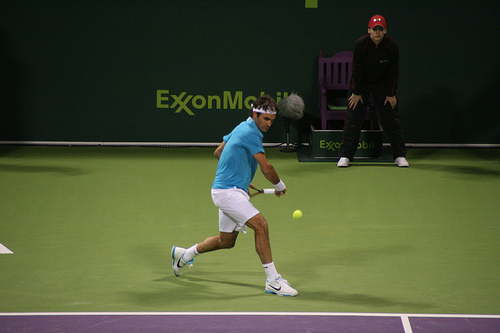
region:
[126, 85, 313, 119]
Exxon Mobile logo in background of sporting event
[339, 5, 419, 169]
man in red baseball cap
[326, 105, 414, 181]
dark pants with white sneakers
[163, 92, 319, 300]
male tennis player wearing white shorts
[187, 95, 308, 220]
man playing tennis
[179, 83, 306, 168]
man playing a sport wearing a white headband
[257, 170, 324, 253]
tennis ball in midair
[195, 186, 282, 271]
male legs dressed in white shorts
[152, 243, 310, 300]
Nike brand sneakers for men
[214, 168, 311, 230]
tennis racket being swung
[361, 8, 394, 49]
a red baseball cay with a white logo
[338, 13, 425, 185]
the tennis game umpire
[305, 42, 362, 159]
A tennis umpire chair sits againt the wall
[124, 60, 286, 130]
a sponsors name on the tennis court wall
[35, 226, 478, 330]
a green and purple tennis court cover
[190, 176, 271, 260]
a man wears white shorts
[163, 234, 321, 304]
white Nike's with white socks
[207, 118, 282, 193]
A robin egg blue tennis shirt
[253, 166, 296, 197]
white wrist band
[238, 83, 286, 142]
a tennis player wears a white sweat band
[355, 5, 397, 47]
man wearing red hat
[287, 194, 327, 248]
yellow tennis ball in air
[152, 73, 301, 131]
advertising on wall on tennis match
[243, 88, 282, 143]
man wearing white head band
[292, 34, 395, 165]
purple judges chair at tennis match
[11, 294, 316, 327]
white line painted on tennis court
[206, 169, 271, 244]
mans white shorts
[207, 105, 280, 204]
light blue mans shirt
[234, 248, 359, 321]
mens white athletic socks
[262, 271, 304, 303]
mens white tennis shoes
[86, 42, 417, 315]
person playing tennis on court.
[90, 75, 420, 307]
man playing tennis on court.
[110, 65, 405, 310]
male playing tennis on court.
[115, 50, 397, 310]
adult playing tennis on court.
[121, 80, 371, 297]
adult person playing tennis on court.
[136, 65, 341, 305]
person striking tennis ball on court.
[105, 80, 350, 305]
player striking tennis ball on court.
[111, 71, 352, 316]
male striking tennis ball on court.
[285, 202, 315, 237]
tennis ball in motion on court.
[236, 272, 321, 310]
right foot planted on court.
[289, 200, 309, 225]
Tennis ball is in mid air.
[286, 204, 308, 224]
Tennis ball is yellow.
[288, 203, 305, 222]
Tennis ball is round.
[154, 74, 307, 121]
Wall on background reads EXXON MOBIL.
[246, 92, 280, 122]
Man is wearing sweat band.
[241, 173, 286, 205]
Man is holding tennis racquet.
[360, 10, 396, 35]
Man is wearing red baseball cap.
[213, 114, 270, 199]
Man is wearing blue shirt.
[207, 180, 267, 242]
Man is wearing white shorts.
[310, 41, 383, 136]
There's a purple bench against back wall.